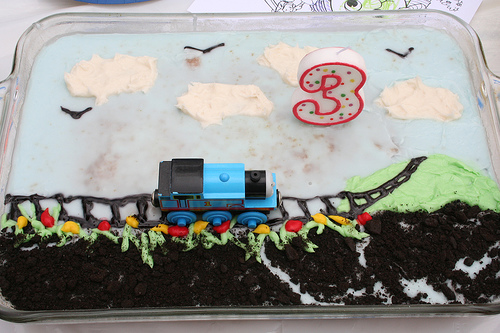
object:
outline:
[290, 59, 365, 127]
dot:
[332, 69, 336, 73]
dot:
[348, 103, 353, 106]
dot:
[340, 113, 344, 116]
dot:
[347, 71, 352, 75]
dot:
[309, 110, 314, 114]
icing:
[173, 81, 275, 129]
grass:
[336, 153, 499, 212]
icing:
[336, 151, 499, 220]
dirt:
[0, 201, 482, 309]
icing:
[4, 154, 427, 228]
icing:
[59, 105, 92, 119]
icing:
[126, 214, 232, 238]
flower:
[40, 206, 55, 227]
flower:
[61, 221, 81, 235]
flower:
[98, 220, 112, 232]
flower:
[167, 224, 189, 238]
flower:
[252, 223, 271, 234]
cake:
[1, 40, 500, 313]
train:
[151, 158, 277, 230]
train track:
[2, 154, 428, 227]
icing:
[60, 220, 80, 236]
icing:
[98, 220, 112, 230]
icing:
[192, 219, 210, 235]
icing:
[284, 218, 303, 233]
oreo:
[418, 291, 429, 299]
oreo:
[463, 257, 474, 266]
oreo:
[240, 272, 260, 287]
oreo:
[18, 233, 41, 250]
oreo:
[307, 226, 319, 240]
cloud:
[372, 77, 463, 124]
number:
[289, 45, 369, 127]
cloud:
[61, 52, 161, 107]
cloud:
[174, 80, 276, 130]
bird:
[58, 104, 92, 119]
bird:
[183, 42, 226, 55]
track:
[0, 154, 427, 227]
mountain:
[337, 153, 500, 213]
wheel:
[166, 210, 197, 227]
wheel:
[202, 211, 233, 227]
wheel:
[237, 212, 268, 229]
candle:
[292, 45, 368, 127]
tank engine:
[152, 155, 282, 229]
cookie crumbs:
[1, 199, 499, 313]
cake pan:
[4, 10, 500, 322]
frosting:
[338, 152, 500, 223]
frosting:
[174, 40, 462, 129]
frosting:
[63, 54, 159, 106]